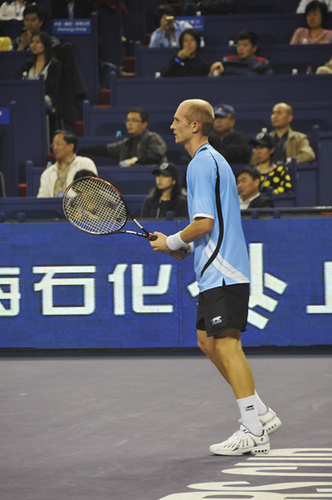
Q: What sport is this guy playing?
A: Tennis.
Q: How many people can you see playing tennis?
A: One.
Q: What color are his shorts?
A: Black.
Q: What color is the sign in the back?
A: Blue.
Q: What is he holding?
A: A racquet.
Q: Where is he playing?
A: A tennis court.